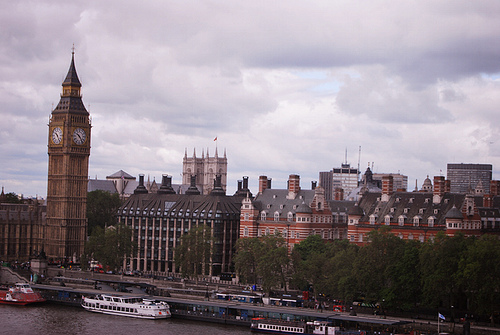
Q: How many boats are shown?
A: 3.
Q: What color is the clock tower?
A: Brown.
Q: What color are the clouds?
A: Grey.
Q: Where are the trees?
A: Along the street.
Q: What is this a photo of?
A: A city.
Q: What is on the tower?
A: A clock.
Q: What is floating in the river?
A: Boats.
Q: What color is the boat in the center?
A: White.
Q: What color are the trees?
A: Green.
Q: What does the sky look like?
A: Cloudy and grey.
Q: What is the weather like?
A: Cloudy and grey.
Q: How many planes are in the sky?
A: Zero.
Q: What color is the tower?
A: Orange.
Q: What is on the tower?
A: Clocks.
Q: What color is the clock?
A: White.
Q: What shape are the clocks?
A: Circle.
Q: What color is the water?
A: Black.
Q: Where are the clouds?
A: In the sky.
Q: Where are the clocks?
A: On the tower.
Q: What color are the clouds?
A: Gray.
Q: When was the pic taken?
A: During the day.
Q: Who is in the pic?
A: No one.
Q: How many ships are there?
A: 3.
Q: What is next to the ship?
A: Train.